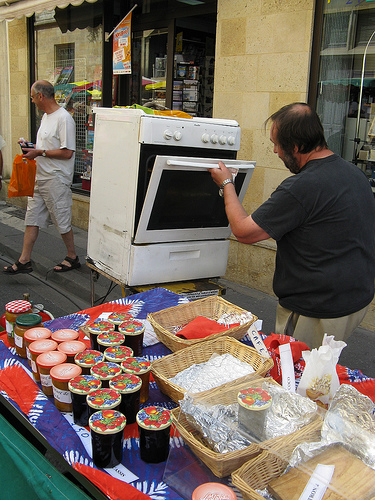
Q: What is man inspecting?
A: Oven.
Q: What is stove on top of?
A: Metal structure.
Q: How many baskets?
A: 4.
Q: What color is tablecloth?
A: Red and blue.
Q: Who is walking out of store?
A: The man.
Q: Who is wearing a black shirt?
A: Man on right.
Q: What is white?
A: An oven.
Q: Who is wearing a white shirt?
A: Man on left.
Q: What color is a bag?
A: Orange.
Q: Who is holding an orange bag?
A: Man on left.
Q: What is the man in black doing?
A: Opening an oven.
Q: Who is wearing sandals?
A: Man in white.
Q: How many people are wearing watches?
A: Two.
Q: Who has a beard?
A: Man in black shirt.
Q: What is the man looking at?
A: An oven.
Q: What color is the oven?
A: White.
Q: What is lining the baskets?
A: Aluminium foil.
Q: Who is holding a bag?
A: Man in white shirt.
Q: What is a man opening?
A: Oven.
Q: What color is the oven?
A: White.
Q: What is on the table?
A: Jars of preserves.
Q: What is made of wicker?
A: Baskets.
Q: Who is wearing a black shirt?
A: Man opening oven.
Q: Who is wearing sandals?
A: Man on left.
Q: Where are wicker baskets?
A: On the table.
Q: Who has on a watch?
A: Man in black.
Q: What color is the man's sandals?
A: Black.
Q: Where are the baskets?
A: On the table.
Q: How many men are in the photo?
A: Two.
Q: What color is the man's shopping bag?
A: Orange.